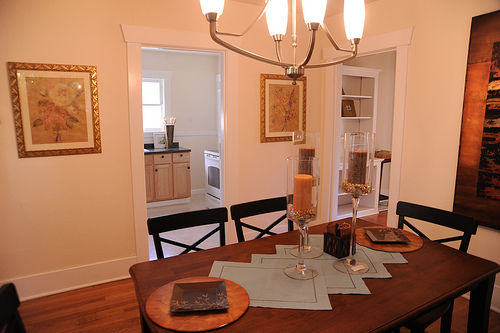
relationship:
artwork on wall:
[257, 68, 308, 139] [15, 9, 334, 252]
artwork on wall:
[6, 56, 99, 152] [15, 9, 334, 252]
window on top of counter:
[136, 79, 170, 132] [141, 138, 193, 207]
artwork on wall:
[5, 60, 102, 160] [5, 158, 140, 289]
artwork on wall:
[260, 70, 308, 143] [5, 158, 140, 289]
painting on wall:
[455, 10, 499, 220] [3, 0, 121, 62]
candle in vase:
[337, 148, 380, 187] [341, 127, 370, 187]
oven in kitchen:
[201, 147, 224, 210] [139, 48, 224, 263]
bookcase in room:
[336, 69, 376, 215] [337, 40, 394, 217]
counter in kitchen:
[307, 238, 428, 323] [138, 95, 222, 187]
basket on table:
[323, 219, 358, 256] [128, 214, 498, 331]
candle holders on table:
[268, 133, 388, 290] [64, 197, 494, 322]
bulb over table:
[263, 0, 288, 37] [143, 203, 496, 330]